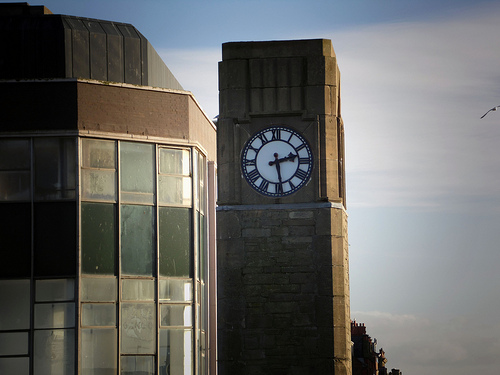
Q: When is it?
A: Day time.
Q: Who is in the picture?
A: No one.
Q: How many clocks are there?
A: One.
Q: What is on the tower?
A: A clock.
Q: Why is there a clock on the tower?
A: To show the time.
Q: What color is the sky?
A: Blue.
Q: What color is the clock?
A: Black and white.